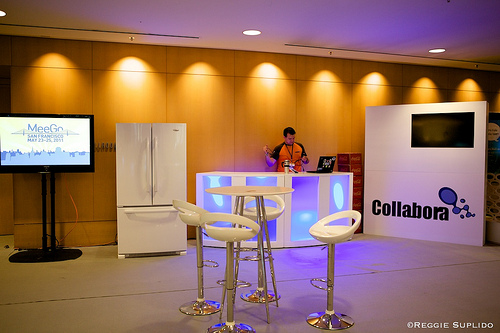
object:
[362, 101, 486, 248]
board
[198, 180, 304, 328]
table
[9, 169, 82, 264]
pedestal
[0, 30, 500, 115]
arches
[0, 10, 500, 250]
wall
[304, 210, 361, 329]
stool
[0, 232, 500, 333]
floor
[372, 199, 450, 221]
"collabora"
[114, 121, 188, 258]
refrigerator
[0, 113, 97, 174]
tv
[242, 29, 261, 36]
light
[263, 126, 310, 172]
man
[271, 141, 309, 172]
shirt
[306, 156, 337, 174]
laptop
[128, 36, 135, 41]
sprinkler